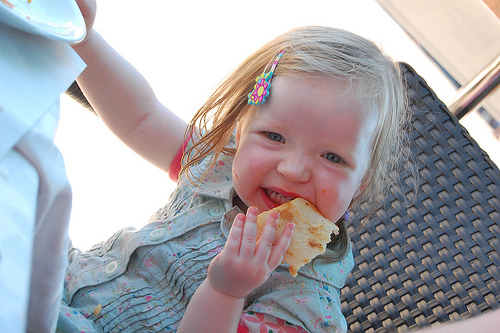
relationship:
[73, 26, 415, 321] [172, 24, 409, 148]
girl with blonde hair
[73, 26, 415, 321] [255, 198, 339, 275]
girl eating food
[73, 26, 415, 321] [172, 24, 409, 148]
girl has blonde hair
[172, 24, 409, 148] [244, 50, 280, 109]
blonde hair with flower band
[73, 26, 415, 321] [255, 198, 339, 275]
girl holding food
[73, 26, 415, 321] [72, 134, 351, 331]
girl wearing blouse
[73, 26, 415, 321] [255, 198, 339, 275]
girl relaxing with food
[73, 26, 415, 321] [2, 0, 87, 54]
girl with plate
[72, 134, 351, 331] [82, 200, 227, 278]
blouse has buttons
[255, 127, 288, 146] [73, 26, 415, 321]
eye of girl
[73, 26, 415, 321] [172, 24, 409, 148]
girl has hair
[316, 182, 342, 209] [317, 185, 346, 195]
cheek has sauce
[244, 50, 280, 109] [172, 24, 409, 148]
flower band in blonde hair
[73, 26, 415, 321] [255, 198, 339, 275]
girl with food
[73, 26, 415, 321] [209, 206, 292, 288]
girl with hand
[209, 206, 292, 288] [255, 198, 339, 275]
hand holding food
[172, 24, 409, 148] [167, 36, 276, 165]
blonde hair has strands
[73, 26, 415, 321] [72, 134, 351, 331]
girl with blouse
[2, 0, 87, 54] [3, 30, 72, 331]
plate on table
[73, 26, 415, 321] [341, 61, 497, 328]
girl in chair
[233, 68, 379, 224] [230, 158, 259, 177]
face has sauce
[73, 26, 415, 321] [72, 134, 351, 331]
girl has blouse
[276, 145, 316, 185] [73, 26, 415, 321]
nose of girl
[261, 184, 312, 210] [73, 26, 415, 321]
mouth of girl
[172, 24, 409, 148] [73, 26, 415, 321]
blonde hair of girl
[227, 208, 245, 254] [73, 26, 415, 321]
finger of girl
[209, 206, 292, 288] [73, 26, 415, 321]
fingers of girl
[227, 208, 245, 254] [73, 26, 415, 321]
finger on girl